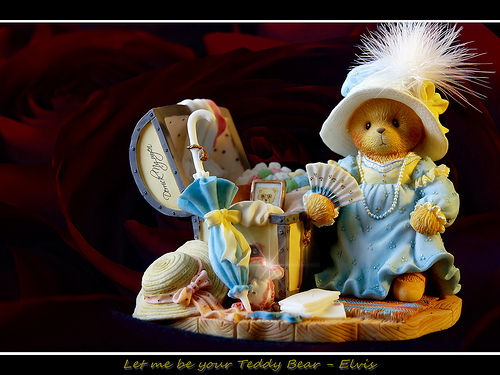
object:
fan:
[303, 161, 366, 224]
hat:
[317, 19, 497, 165]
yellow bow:
[418, 79, 449, 135]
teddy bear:
[283, 21, 500, 305]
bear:
[256, 185, 278, 205]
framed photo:
[247, 179, 287, 210]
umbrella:
[176, 108, 256, 314]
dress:
[292, 149, 463, 302]